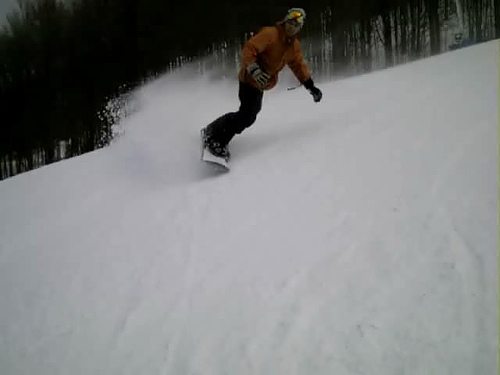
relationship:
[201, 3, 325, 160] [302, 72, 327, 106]
person wearing glove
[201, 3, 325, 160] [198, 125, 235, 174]
person on top of snowboard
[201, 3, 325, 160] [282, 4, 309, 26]
person wearing hat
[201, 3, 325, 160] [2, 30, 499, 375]
person on side of hill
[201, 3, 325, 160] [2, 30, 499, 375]
person tilted towards hill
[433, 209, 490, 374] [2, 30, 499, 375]
track in hill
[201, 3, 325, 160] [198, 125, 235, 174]
person riding snowboard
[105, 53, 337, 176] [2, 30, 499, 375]
snow on top of hill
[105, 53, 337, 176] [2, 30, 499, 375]
snow on hill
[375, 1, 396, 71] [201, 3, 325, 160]
tree behind person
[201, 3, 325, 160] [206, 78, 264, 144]
person wearing pants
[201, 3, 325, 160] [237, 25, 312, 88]
person wearing jacket